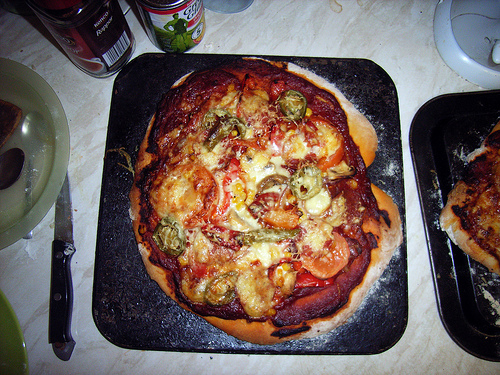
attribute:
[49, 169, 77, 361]
knife — dirty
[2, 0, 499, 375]
table — white, marble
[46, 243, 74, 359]
handle — black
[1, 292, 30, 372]
plate — green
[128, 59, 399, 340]
pizza — burned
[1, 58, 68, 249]
plate — transparent, beige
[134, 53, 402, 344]
crust — crispy, burned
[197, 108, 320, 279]
middle — cheesy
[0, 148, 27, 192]
spoon — silver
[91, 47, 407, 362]
pan — square, black, dark, silver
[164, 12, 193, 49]
giant — green